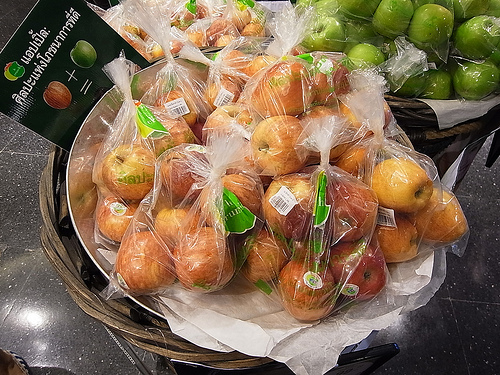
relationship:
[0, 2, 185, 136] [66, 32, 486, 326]
sign says apple sale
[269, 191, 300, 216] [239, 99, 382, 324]
tag on bag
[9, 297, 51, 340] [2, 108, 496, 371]
light on floor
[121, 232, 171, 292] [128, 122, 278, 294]
fruit in bag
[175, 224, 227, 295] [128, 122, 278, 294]
fruit in bag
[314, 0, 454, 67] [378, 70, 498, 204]
apples in baskets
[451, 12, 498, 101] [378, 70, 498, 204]
apples in baskets